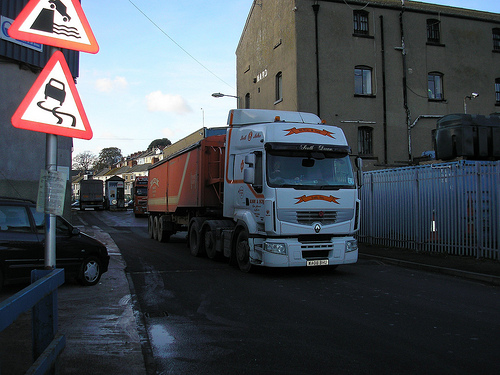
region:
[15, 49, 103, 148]
a red and white sign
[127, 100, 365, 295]
an orange and white truck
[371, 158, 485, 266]
a white fence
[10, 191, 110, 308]
a black car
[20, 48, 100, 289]
a red and white sign on a pole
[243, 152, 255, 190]
mirrors on the truck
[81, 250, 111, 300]
tire on the car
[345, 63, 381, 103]
window in the building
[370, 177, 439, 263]
fence next to the street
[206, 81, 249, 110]
a light over the street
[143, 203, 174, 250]
tires on a truck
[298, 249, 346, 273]
a tag on the truck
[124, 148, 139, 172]
a chimney on the building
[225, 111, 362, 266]
White cab on a truck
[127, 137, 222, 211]
Orange box on the back of a truck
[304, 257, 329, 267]
A white license plate on a truck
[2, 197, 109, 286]
A black minivan near a street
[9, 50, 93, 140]
Triangle shaped warning sign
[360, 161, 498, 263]
A white fence near a truck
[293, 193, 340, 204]
A ribbon shape painted on a truck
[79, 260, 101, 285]
The front tire on a black minivan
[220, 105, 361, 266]
The white cab of a big truck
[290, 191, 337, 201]
Orange ribbon decal on a white truck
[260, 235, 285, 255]
Headlight on the front of a truck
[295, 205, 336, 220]
Front grill on a truck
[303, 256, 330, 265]
A white license plate on a truck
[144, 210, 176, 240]
Back tires on a truck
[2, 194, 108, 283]
A black minivan near the street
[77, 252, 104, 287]
Front tire on a truck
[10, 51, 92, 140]
A triangle shaped sign on a pole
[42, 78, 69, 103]
Black image of a car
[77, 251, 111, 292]
a tire on a car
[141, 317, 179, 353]
water on the street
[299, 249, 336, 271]
a tag on the truck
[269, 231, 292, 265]
a light on the truck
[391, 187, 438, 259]
a fence next to the street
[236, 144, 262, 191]
mirrors on the truck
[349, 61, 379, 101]
window in a building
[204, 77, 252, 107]
a light above the street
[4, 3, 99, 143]
a red and white sign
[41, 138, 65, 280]
a silver pole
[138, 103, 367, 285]
a truck on the road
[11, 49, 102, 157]
red and white metal sign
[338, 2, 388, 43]
window on side of building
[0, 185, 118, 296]
black vehicle on sidewalk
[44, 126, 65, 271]
silver metal sign post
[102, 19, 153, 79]
clear blue cloudless sky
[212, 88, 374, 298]
white large truck cab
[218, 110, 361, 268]
a truck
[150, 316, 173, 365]
a puddle of water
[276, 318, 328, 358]
the street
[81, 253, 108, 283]
front tire of the car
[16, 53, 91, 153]
a triangle sign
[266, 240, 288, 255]
headlight of the truck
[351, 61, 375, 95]
a window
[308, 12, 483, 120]
a brown building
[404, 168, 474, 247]
a fence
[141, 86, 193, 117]
a white cloud in the sky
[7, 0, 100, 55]
sign is triangular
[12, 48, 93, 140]
sign is triangular